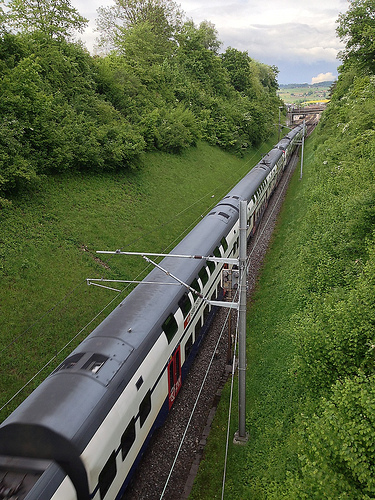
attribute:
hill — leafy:
[0, 101, 286, 430]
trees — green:
[0, 2, 285, 203]